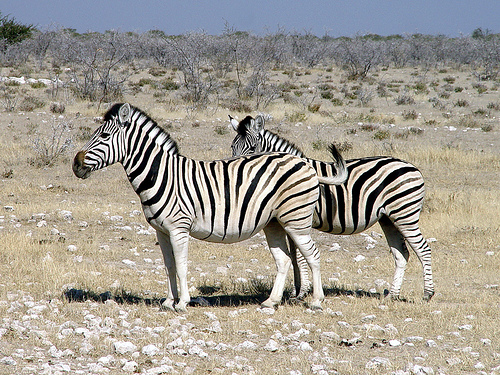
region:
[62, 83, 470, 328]
Two zebras standing on plain.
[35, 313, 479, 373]
Small rocks covering ground.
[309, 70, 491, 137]
Scrub bush growing on ground.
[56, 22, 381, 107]
Bare trees growing in background.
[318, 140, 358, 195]
Zebra's long tail with black tip.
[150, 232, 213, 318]
Zebra's two front legs.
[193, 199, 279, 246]
Zebra's fat round stomach.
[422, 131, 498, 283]
Patchy brown grass on groound.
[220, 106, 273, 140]
A zebra's two ears.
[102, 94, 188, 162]
Zebra mane running from forehead down back of neck.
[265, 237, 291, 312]
the inside of the zebras leg is white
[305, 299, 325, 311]
the hoof is black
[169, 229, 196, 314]
this leg has faded black stripes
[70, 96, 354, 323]
the zebra is striped black, white and tan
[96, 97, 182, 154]
the mane is black and white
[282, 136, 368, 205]
its tail is wagging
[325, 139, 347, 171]
the tail has a black tip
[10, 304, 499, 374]
the ground is rocky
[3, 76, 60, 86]
the rocks are white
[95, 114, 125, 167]
the stripes on the face go many directions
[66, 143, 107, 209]
Zebra has black nose.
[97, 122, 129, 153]
Zebra has dark eye.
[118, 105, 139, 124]
Zebra has white ear.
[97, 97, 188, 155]
Zebra has black and white hair on mane.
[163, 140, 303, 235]
Zebra is black and white.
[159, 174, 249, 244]
Zebra is covered in stripes.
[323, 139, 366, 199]
Tip of tail is black on zebra.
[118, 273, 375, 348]
Zebra is standing in field.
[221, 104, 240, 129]
Tip of zebra's ear is black.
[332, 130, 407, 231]
Zebra has black and white stripes.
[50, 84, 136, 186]
face of the zebra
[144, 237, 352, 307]
legs of the zebra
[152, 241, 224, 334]
front two legs of zebra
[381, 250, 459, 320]
back two legs of zebra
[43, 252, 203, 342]
shadow of the zebra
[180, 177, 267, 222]
skin of the zebra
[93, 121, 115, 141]
eye of the zebra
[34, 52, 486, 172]
all dry trees on back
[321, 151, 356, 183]
tail of the zebra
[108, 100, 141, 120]
ear of the zebra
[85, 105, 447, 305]
Two zebras standing in the plains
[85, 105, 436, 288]
The zebras are black and white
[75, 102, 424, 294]
The zebras have stripes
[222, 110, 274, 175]
The zebra's face is hidden behind the other zebra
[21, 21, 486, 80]
Dead shrubbery in the distance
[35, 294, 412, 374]
Small rocks in front of the zebras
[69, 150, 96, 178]
The zebras nose is brown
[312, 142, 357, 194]
The zebra's tail is wagging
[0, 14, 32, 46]
A lone green plant behind the zebras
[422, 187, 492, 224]
The grass is dead